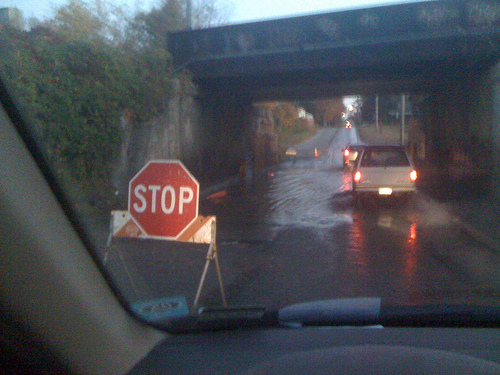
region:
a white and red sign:
[130, 156, 197, 237]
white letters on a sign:
[131, 179, 192, 214]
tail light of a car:
[351, 169, 359, 183]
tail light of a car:
[409, 169, 416, 184]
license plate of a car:
[377, 186, 394, 197]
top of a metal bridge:
[158, 3, 498, 97]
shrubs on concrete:
[2, 8, 177, 214]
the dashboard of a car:
[143, 328, 498, 370]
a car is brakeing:
[342, 141, 363, 167]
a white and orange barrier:
[98, 208, 227, 306]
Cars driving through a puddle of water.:
[223, 145, 458, 232]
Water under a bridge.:
[117, 0, 499, 231]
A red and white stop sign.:
[129, 158, 199, 240]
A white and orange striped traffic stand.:
[107, 211, 228, 312]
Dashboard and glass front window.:
[1, 0, 499, 373]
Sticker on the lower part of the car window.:
[129, 296, 194, 325]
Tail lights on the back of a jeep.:
[350, 166, 420, 181]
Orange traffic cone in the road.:
[307, 142, 322, 162]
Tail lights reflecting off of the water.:
[346, 206, 423, 314]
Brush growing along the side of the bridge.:
[0, 0, 235, 239]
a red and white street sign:
[103, 152, 217, 299]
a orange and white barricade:
[96, 205, 223, 290]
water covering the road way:
[239, 153, 323, 248]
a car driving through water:
[315, 108, 485, 223]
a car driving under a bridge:
[318, 94, 474, 219]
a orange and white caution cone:
[305, 138, 319, 165]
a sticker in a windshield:
[124, 280, 197, 335]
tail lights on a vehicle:
[350, 166, 425, 185]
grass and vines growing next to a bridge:
[60, 91, 167, 207]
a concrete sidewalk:
[442, 180, 477, 232]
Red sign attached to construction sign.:
[128, 163, 207, 244]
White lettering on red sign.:
[135, 183, 220, 223]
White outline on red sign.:
[119, 153, 236, 249]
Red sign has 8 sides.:
[129, 165, 224, 256]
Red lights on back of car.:
[344, 166, 427, 195]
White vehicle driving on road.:
[346, 139, 437, 199]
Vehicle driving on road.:
[332, 137, 365, 164]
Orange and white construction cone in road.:
[311, 138, 329, 173]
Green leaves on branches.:
[43, 60, 96, 112]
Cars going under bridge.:
[181, 16, 460, 216]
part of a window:
[308, 224, 339, 263]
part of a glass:
[366, 189, 380, 214]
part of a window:
[297, 154, 352, 234]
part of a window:
[317, 241, 360, 306]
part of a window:
[298, 269, 324, 300]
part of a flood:
[315, 235, 342, 262]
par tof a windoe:
[296, 276, 313, 306]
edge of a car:
[359, 179, 370, 197]